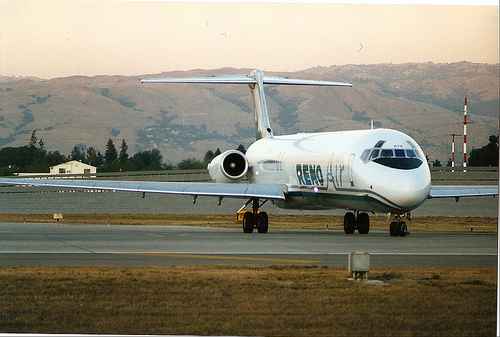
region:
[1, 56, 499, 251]
plane on the tarmac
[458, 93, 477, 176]
red and white stripes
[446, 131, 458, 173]
pole is red and white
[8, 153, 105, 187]
white building in the disance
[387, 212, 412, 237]
front wheels are down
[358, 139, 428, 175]
windows around the cockpit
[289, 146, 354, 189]
logo on the side of the plane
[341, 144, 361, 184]
door on the front of the plane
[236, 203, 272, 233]
wheels under the plane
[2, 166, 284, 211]
long and thin wing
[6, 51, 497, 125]
mountains in the background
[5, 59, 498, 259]
the plane on the runway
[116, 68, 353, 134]
the tail of the plane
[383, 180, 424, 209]
the nose of the plane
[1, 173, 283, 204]
the wing of the plane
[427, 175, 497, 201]
the wing of the plane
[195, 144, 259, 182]
the engine of the plane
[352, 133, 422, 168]
the cockpit of the plane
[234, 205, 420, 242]
the landing gear is down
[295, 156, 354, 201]
writing on the plane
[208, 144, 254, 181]
a white plane engine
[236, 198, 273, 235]
big black tires on a plane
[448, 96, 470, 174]
red and white airport markers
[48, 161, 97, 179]
a white office building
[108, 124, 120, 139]
green trees on the mountain side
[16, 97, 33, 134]
green trees on the mountain side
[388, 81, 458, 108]
green trees on the mountain side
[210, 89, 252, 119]
green trees on the mountain side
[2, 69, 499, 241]
a white jet plane on runway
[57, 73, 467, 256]
airplane on the runway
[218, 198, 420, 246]
landing gear of the airplane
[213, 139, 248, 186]
engine of the airplane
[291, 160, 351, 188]
airline name on the airplane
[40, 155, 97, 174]
building behind the runways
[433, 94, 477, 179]
red and white striped poles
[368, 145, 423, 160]
cockpit windows of the plane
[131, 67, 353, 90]
tail wing of the plane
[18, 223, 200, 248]
runway at the airport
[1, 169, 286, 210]
wing of the plane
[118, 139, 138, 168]
A tree in a field